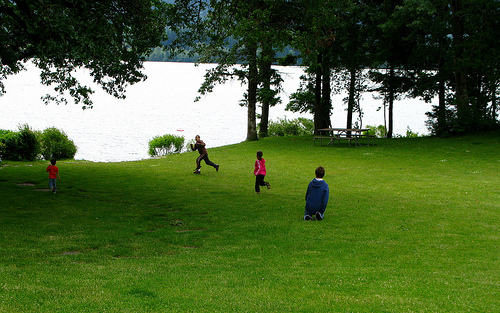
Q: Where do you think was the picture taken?
A: It was taken at the park.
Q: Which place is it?
A: It is a park.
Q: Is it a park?
A: Yes, it is a park.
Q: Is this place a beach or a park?
A: It is a park.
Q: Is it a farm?
A: No, it is a park.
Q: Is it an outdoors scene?
A: Yes, it is outdoors.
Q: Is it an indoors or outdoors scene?
A: It is outdoors.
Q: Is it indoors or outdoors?
A: It is outdoors.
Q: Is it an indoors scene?
A: No, it is outdoors.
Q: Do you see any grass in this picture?
A: Yes, there is grass.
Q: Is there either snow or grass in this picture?
A: Yes, there is grass.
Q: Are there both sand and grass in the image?
A: No, there is grass but no sand.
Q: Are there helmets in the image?
A: No, there are no helmets.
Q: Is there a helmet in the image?
A: No, there are no helmets.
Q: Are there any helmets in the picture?
A: No, there are no helmets.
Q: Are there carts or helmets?
A: No, there are no helmets or carts.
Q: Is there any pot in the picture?
A: No, there are no pots.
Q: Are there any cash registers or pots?
A: No, there are no pots or cash registers.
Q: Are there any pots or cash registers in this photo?
A: No, there are no pots or cash registers.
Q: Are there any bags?
A: No, there are no bags.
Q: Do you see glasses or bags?
A: No, there are no bags or glasses.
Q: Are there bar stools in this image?
A: No, there are no bar stools.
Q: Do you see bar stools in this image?
A: No, there are no bar stools.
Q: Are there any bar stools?
A: No, there are no bar stools.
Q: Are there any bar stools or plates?
A: No, there are no bar stools or plates.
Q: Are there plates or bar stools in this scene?
A: No, there are no bar stools or plates.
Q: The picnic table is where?
A: The picnic table is in the park.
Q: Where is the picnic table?
A: The picnic table is in the park.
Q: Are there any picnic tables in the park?
A: Yes, there is a picnic table in the park.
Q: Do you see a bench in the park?
A: No, there is a picnic table in the park.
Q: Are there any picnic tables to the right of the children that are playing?
A: Yes, there is a picnic table to the right of the kids.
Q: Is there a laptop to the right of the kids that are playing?
A: No, there is a picnic table to the right of the children.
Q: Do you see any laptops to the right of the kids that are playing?
A: No, there is a picnic table to the right of the children.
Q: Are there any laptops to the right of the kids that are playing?
A: No, there is a picnic table to the right of the children.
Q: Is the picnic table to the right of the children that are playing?
A: Yes, the picnic table is to the right of the children.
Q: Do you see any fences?
A: No, there are no fences.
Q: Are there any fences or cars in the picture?
A: No, there are no fences or cars.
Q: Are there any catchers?
A: No, there are no catchers.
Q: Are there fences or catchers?
A: No, there are no catchers or fences.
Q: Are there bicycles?
A: No, there are no bicycles.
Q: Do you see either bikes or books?
A: No, there are no bikes or books.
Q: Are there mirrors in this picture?
A: No, there are no mirrors.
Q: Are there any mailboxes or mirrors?
A: No, there are no mirrors or mailboxes.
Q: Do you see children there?
A: Yes, there is a child.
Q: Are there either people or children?
A: Yes, there is a child.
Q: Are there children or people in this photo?
A: Yes, there is a child.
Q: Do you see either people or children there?
A: Yes, there is a child.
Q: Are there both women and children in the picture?
A: No, there is a child but no women.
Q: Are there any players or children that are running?
A: Yes, the child is running.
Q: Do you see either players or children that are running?
A: Yes, the child is running.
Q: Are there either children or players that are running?
A: Yes, the child is running.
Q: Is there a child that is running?
A: Yes, there is a child that is running.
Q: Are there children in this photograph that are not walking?
A: Yes, there is a child that is running.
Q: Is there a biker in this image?
A: No, there are no bikers.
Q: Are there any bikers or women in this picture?
A: No, there are no bikers or women.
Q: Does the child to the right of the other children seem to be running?
A: Yes, the kid is running.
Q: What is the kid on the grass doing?
A: The kid is running.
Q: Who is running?
A: The kid is running.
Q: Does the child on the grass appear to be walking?
A: No, the kid is running.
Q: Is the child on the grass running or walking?
A: The kid is running.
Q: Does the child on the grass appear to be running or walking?
A: The kid is running.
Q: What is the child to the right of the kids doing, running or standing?
A: The kid is running.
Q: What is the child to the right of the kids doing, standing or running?
A: The kid is running.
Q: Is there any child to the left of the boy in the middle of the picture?
A: Yes, there is a child to the left of the boy.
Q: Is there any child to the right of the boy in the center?
A: No, the child is to the left of the boy.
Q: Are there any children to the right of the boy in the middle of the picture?
A: No, the child is to the left of the boy.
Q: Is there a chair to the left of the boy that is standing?
A: No, there is a child to the left of the boy.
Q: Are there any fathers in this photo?
A: No, there are no fathers.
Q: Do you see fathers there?
A: No, there are no fathers.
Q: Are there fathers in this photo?
A: No, there are no fathers.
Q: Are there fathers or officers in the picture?
A: No, there are no fathers or officers.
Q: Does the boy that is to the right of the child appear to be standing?
A: Yes, the boy is standing.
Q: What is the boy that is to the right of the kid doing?
A: The boy is standing.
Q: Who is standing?
A: The boy is standing.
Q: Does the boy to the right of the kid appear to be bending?
A: No, the boy is standing.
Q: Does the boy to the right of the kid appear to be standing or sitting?
A: The boy is standing.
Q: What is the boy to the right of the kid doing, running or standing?
A: The boy is standing.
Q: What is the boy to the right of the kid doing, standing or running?
A: The boy is standing.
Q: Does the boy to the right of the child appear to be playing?
A: Yes, the boy is playing.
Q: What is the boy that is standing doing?
A: The boy is playing.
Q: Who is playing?
A: The boy is playing.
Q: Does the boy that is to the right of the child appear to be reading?
A: No, the boy is playing.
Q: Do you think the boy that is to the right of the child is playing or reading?
A: The boy is playing.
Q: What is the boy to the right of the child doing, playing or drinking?
A: The boy is playing.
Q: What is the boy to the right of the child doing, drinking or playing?
A: The boy is playing.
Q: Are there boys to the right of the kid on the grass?
A: Yes, there is a boy to the right of the child.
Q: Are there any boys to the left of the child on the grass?
A: No, the boy is to the right of the child.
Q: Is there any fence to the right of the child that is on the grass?
A: No, there is a boy to the right of the child.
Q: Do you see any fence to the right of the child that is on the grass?
A: No, there is a boy to the right of the child.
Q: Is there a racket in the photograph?
A: No, there are no rackets.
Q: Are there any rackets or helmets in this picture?
A: No, there are no rackets or helmets.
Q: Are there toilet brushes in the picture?
A: No, there are no toilet brushes.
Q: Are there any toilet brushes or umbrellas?
A: No, there are no toilet brushes or umbrellas.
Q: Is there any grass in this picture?
A: Yes, there is grass.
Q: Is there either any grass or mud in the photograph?
A: Yes, there is grass.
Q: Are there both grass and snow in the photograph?
A: No, there is grass but no snow.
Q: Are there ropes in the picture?
A: No, there are no ropes.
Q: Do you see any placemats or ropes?
A: No, there are no ropes or placemats.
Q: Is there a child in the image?
A: Yes, there are children.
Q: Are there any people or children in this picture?
A: Yes, there are children.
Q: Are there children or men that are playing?
A: Yes, the children are playing.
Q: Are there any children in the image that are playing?
A: Yes, there are children that are playing.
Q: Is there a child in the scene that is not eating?
A: Yes, there are children that are playing.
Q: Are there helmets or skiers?
A: No, there are no helmets or skiers.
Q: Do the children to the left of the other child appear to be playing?
A: Yes, the children are playing.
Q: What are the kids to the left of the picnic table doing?
A: The kids are playing.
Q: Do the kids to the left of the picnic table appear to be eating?
A: No, the children are playing.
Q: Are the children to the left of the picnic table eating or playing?
A: The kids are playing.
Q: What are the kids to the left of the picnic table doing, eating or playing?
A: The kids are playing.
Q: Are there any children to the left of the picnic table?
A: Yes, there are children to the left of the picnic table.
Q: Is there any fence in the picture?
A: No, there are no fences.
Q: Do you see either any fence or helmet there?
A: No, there are no fences or helmets.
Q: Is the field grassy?
A: Yes, the field is grassy.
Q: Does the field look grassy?
A: Yes, the field is grassy.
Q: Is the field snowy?
A: No, the field is grassy.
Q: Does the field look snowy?
A: No, the field is grassy.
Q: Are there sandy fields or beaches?
A: No, there is a field but it is grassy.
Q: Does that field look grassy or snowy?
A: The field is grassy.